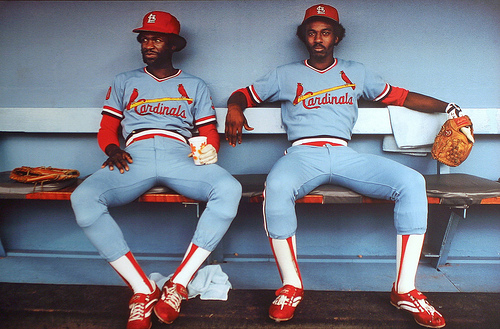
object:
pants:
[70, 137, 242, 277]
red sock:
[390, 226, 428, 296]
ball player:
[223, 4, 476, 326]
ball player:
[67, 2, 241, 327]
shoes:
[125, 281, 161, 327]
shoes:
[266, 280, 306, 322]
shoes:
[388, 279, 446, 327]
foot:
[264, 279, 308, 322]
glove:
[432, 101, 485, 146]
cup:
[186, 135, 210, 165]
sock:
[106, 247, 159, 297]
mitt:
[429, 112, 479, 168]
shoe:
[152, 278, 185, 327]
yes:
[314, 5, 328, 14]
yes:
[145, 12, 157, 23]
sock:
[165, 241, 211, 285]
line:
[288, 258, 305, 288]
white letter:
[145, 4, 326, 24]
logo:
[289, 69, 360, 111]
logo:
[121, 86, 197, 120]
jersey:
[240, 59, 412, 146]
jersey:
[95, 69, 219, 157]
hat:
[302, 4, 340, 26]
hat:
[131, 10, 179, 35]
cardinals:
[301, 90, 356, 110]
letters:
[337, 95, 349, 106]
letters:
[138, 105, 147, 113]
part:
[286, 234, 299, 294]